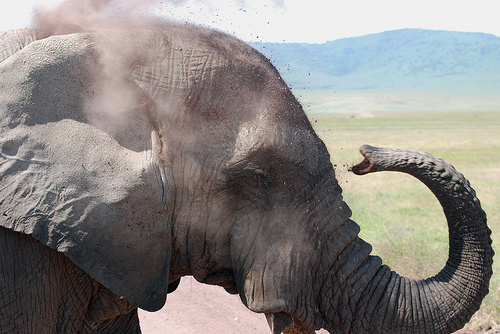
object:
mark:
[127, 223, 133, 229]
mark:
[106, 159, 111, 163]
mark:
[127, 200, 131, 203]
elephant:
[0, 16, 495, 334]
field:
[291, 91, 500, 333]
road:
[137, 274, 273, 333]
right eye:
[255, 173, 276, 186]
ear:
[0, 31, 173, 312]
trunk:
[308, 143, 494, 334]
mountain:
[246, 28, 498, 95]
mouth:
[230, 232, 324, 334]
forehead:
[207, 28, 322, 142]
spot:
[152, 292, 160, 299]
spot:
[116, 271, 125, 276]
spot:
[99, 263, 109, 271]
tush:
[262, 310, 297, 334]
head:
[102, 21, 327, 284]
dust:
[28, 0, 186, 137]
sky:
[153, 0, 499, 45]